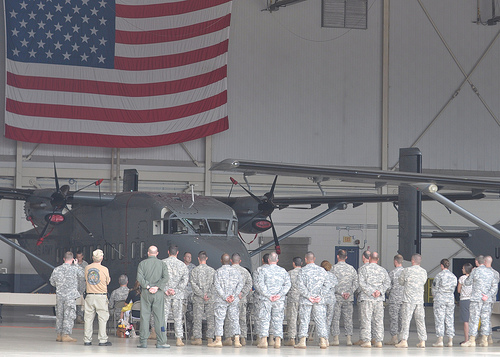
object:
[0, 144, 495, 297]
plane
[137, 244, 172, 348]
men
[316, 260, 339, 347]
women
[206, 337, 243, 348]
boots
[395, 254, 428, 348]
soldier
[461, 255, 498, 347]
soldier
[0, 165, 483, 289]
airplane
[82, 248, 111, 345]
person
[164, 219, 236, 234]
window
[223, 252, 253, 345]
soldier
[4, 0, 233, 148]
american flag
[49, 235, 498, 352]
line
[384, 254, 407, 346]
soldiers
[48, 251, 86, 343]
serviceman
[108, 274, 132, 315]
serviceman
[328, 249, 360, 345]
serviceman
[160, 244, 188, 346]
serviceman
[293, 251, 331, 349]
serviceman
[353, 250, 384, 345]
serviceman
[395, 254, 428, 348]
serviceman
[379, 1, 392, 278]
pole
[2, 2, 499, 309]
building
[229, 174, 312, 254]
propeller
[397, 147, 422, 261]
pillar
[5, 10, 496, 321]
hangar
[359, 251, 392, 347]
serviceman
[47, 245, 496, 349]
group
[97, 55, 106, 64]
star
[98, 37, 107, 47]
star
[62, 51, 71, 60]
star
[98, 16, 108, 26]
star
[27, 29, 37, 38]
star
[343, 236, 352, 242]
sign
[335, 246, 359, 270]
door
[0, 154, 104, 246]
propellar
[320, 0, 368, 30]
window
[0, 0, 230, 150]
flag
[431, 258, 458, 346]
serviceman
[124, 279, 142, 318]
woman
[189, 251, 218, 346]
soldier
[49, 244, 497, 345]
line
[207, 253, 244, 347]
man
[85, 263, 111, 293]
shirt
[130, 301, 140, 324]
chair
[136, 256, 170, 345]
uniform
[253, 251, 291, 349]
serviceman